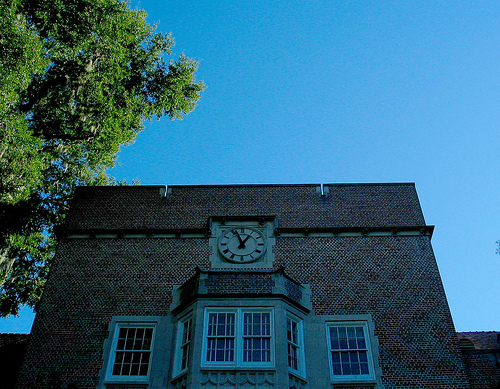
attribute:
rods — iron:
[209, 312, 234, 359]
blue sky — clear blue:
[113, 3, 494, 328]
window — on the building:
[285, 312, 304, 372]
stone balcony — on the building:
[174, 257, 313, 318]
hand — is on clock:
[238, 235, 250, 252]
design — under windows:
[166, 366, 315, 388]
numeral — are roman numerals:
[251, 228, 266, 243]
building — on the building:
[55, 176, 440, 387]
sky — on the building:
[2, 5, 497, 334]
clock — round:
[216, 224, 266, 264]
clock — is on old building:
[213, 210, 280, 271]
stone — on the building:
[317, 247, 342, 273]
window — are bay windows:
[202, 301, 278, 378]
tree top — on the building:
[2, 0, 204, 315]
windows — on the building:
[179, 290, 399, 380]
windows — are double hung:
[62, 197, 412, 342]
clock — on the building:
[207, 212, 299, 277]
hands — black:
[233, 227, 251, 250]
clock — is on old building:
[215, 224, 267, 260]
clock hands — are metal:
[232, 229, 251, 251]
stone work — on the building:
[382, 237, 442, 386]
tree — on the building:
[4, 44, 174, 149]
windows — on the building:
[284, 311, 308, 378]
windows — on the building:
[110, 299, 371, 374]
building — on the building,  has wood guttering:
[16, 176, 472, 388]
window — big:
[204, 308, 273, 365]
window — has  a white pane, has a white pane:
[328, 318, 375, 385]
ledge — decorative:
[172, 366, 311, 386]